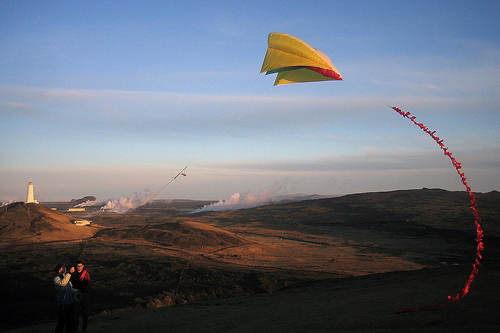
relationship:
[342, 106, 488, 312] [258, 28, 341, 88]
tassel on kite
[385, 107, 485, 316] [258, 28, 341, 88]
kite tail on kite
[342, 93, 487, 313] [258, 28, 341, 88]
tassel on kite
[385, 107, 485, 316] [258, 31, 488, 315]
kite tail on kite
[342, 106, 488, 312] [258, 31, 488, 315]
tassel on kite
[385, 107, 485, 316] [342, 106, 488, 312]
kite tail a tassel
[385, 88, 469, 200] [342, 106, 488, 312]
kite tail a tassel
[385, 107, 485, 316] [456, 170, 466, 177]
kite tail a tassel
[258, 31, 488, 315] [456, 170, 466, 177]
kite has a tassel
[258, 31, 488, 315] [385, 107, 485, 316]
kite has a kite tail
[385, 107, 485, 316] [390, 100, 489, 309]
kite tail a red tassel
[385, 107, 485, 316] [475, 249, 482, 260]
kite tail a tassel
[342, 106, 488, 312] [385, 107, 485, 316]
tassel a kite tail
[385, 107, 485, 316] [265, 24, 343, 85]
kite tail on a kite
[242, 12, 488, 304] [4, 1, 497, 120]
kite in air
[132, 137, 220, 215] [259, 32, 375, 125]
line holding kite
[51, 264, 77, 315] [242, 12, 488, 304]
man flying kite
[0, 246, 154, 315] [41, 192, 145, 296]
fog coming from ground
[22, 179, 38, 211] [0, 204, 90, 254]
lighthouse in hill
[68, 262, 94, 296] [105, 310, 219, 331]
man on ground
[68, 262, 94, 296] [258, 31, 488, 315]
man flying kite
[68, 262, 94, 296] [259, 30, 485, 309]
man flying kite